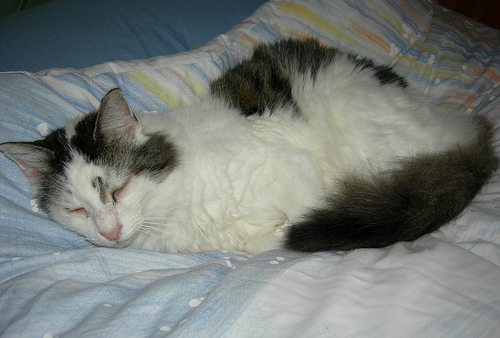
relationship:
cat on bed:
[14, 72, 472, 271] [96, 6, 126, 45]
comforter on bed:
[219, 23, 238, 27] [96, 6, 126, 45]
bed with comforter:
[96, 6, 126, 45] [219, 23, 238, 27]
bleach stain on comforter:
[390, 26, 483, 104] [219, 23, 238, 27]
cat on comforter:
[14, 72, 472, 271] [219, 23, 238, 27]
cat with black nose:
[14, 72, 472, 271] [98, 223, 134, 243]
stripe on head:
[56, 120, 104, 165] [15, 139, 181, 219]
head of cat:
[15, 139, 181, 219] [14, 72, 472, 271]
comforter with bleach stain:
[219, 23, 238, 27] [390, 26, 483, 104]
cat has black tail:
[14, 72, 472, 271] [286, 163, 490, 235]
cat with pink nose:
[14, 72, 472, 271] [90, 216, 135, 224]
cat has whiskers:
[14, 72, 472, 271] [147, 213, 194, 241]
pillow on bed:
[371, 24, 455, 63] [96, 6, 126, 45]